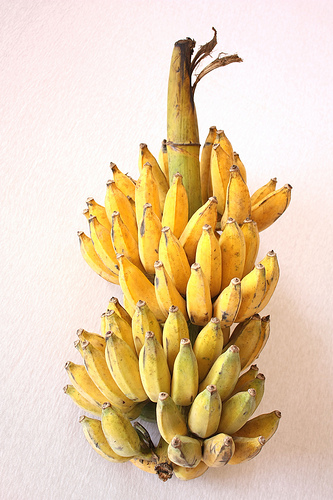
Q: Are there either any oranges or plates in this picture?
A: No, there are no oranges or plates.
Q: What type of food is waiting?
A: The food is plantains.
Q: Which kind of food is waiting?
A: The food is plantains.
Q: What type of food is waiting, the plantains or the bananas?
A: The plantains is waiting.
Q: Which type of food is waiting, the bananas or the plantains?
A: The plantains is waiting.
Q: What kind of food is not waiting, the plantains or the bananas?
A: The bananas is not waiting.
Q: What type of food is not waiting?
A: The food is bananas.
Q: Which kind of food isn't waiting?
A: The food is bananas.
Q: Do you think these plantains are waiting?
A: Yes, the plantains are waiting.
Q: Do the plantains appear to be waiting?
A: Yes, the plantains are waiting.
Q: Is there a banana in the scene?
A: Yes, there are bananas.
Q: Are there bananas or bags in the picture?
A: Yes, there are bananas.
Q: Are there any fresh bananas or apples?
A: Yes, there are fresh bananas.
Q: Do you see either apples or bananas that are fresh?
A: Yes, the bananas are fresh.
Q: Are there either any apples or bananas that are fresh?
A: Yes, the bananas are fresh.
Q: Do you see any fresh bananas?
A: Yes, there are fresh bananas.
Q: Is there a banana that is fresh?
A: Yes, there are bananas that are fresh.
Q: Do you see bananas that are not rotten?
A: Yes, there are fresh bananas.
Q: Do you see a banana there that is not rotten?
A: Yes, there are fresh bananas.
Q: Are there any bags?
A: No, there are no bags.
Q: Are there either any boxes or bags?
A: No, there are no bags or boxes.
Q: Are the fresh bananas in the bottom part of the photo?
A: Yes, the bananas are in the bottom of the image.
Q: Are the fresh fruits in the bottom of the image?
A: Yes, the bananas are in the bottom of the image.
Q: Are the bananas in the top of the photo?
A: No, the bananas are in the bottom of the image.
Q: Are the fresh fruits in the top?
A: No, the bananas are in the bottom of the image.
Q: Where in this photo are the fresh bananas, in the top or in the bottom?
A: The bananas are in the bottom of the image.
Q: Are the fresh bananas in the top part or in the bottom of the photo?
A: The bananas are in the bottom of the image.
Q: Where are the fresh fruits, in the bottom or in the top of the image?
A: The bananas are in the bottom of the image.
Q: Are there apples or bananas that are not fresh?
A: No, there are bananas but they are fresh.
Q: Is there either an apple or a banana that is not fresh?
A: No, there are bananas but they are fresh.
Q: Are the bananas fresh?
A: Yes, the bananas are fresh.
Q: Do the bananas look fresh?
A: Yes, the bananas are fresh.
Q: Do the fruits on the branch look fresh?
A: Yes, the bananas are fresh.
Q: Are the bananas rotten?
A: No, the bananas are fresh.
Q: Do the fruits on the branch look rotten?
A: No, the bananas are fresh.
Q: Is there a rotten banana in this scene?
A: No, there are bananas but they are fresh.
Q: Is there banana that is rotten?
A: No, there are bananas but they are fresh.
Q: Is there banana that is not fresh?
A: No, there are bananas but they are fresh.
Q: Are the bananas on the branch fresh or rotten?
A: The bananas are fresh.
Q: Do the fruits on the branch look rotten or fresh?
A: The bananas are fresh.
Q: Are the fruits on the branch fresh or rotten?
A: The bananas are fresh.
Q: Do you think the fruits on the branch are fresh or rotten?
A: The bananas are fresh.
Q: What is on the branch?
A: The bananas are on the branch.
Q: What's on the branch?
A: The bananas are on the branch.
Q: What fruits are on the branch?
A: The fruits are bananas.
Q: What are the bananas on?
A: The bananas are on the branch.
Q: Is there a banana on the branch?
A: Yes, there are bananas on the branch.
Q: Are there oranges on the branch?
A: No, there are bananas on the branch.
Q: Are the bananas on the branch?
A: Yes, the bananas are on the branch.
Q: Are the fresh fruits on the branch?
A: Yes, the bananas are on the branch.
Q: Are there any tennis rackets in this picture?
A: No, there are no tennis rackets.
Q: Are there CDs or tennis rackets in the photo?
A: No, there are no tennis rackets or cds.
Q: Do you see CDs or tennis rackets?
A: No, there are no tennis rackets or cds.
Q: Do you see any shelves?
A: No, there are no shelves.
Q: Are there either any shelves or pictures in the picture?
A: No, there are no shelves or pictures.